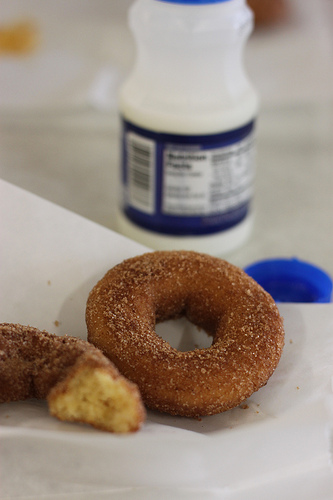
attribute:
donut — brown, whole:
[80, 238, 293, 430]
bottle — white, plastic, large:
[101, 0, 267, 263]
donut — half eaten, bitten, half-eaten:
[0, 308, 155, 441]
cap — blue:
[147, 0, 240, 10]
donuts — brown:
[0, 239, 294, 445]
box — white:
[4, 178, 332, 497]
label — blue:
[112, 107, 264, 242]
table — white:
[0, 54, 331, 284]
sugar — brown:
[0, 246, 292, 391]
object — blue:
[243, 243, 332, 308]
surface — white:
[2, 174, 140, 263]